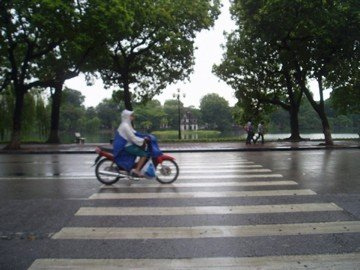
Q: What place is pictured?
A: It is a road.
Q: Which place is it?
A: It is a road.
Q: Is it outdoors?
A: Yes, it is outdoors.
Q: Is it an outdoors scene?
A: Yes, it is outdoors.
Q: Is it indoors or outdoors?
A: It is outdoors.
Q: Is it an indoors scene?
A: No, it is outdoors.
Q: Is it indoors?
A: No, it is outdoors.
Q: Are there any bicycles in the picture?
A: Yes, there is a bicycle.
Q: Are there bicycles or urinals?
A: Yes, there is a bicycle.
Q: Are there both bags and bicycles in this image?
A: Yes, there are both a bicycle and a bag.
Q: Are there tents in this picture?
A: No, there are no tents.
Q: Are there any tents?
A: No, there are no tents.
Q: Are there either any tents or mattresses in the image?
A: No, there are no tents or mattresses.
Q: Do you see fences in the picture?
A: No, there are no fences.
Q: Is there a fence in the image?
A: No, there are no fences.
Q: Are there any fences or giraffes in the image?
A: No, there are no fences or giraffes.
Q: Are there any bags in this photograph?
A: Yes, there is a bag.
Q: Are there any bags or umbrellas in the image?
A: Yes, there is a bag.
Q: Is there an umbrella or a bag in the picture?
A: Yes, there is a bag.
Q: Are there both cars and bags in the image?
A: No, there is a bag but no cars.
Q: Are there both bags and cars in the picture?
A: No, there is a bag but no cars.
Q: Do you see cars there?
A: No, there are no cars.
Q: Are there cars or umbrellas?
A: No, there are no cars or umbrellas.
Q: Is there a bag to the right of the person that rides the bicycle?
A: Yes, there is a bag to the right of the person.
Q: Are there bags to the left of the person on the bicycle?
A: No, the bag is to the right of the person.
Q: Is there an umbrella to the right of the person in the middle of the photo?
A: No, there is a bag to the right of the person.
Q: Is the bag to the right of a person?
A: Yes, the bag is to the right of a person.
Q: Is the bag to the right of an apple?
A: No, the bag is to the right of a person.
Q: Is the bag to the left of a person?
A: No, the bag is to the right of a person.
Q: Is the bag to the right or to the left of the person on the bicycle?
A: The bag is to the right of the person.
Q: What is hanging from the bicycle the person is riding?
A: The bag is hanging from the bicycle.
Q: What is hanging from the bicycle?
A: The bag is hanging from the bicycle.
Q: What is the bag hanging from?
A: The bag is hanging from the bicycle.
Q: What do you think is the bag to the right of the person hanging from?
A: The bag is hanging from the bicycle.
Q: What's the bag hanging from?
A: The bag is hanging from the bicycle.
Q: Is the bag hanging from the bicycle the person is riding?
A: Yes, the bag is hanging from the bicycle.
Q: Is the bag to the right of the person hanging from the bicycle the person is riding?
A: Yes, the bag is hanging from the bicycle.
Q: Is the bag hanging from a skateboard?
A: No, the bag is hanging from the bicycle.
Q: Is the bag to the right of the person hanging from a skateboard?
A: No, the bag is hanging from the bicycle.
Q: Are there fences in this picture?
A: No, there are no fences.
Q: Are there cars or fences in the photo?
A: No, there are no fences or cars.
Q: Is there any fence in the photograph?
A: No, there are no fences.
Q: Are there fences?
A: No, there are no fences.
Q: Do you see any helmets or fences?
A: No, there are no fences or helmets.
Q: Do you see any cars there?
A: No, there are no cars.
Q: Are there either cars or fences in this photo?
A: No, there are no cars or fences.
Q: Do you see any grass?
A: Yes, there is grass.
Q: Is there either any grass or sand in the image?
A: Yes, there is grass.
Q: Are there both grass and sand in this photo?
A: No, there is grass but no sand.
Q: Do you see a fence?
A: No, there are no fences.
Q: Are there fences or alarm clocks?
A: No, there are no fences or alarm clocks.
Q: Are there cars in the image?
A: No, there are no cars.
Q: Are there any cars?
A: No, there are no cars.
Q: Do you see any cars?
A: No, there are no cars.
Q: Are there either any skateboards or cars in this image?
A: No, there are no cars or skateboards.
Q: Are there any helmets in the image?
A: No, there are no helmets.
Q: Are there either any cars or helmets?
A: No, there are no helmets or cars.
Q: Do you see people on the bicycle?
A: Yes, there is a person on the bicycle.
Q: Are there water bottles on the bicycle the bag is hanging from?
A: No, there is a person on the bicycle.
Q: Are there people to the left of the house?
A: Yes, there is a person to the left of the house.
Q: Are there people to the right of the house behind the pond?
A: No, the person is to the left of the house.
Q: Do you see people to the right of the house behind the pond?
A: No, the person is to the left of the house.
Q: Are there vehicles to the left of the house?
A: No, there is a person to the left of the house.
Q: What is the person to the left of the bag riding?
A: The person is riding the bicycle.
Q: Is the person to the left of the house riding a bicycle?
A: Yes, the person is riding a bicycle.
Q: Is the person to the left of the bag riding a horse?
A: No, the person is riding a bicycle.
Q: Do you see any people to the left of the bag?
A: Yes, there is a person to the left of the bag.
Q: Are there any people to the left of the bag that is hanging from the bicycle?
A: Yes, there is a person to the left of the bag.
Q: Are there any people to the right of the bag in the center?
A: No, the person is to the left of the bag.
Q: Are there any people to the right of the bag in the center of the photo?
A: No, the person is to the left of the bag.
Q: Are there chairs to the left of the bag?
A: No, there is a person to the left of the bag.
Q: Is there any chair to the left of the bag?
A: No, there is a person to the left of the bag.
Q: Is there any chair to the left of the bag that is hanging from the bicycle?
A: No, there is a person to the left of the bag.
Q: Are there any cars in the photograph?
A: No, there are no cars.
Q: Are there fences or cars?
A: No, there are no cars or fences.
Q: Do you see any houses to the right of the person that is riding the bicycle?
A: Yes, there is a house to the right of the person.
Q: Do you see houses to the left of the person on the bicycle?
A: No, the house is to the right of the person.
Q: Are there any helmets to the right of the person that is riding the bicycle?
A: No, there is a house to the right of the person.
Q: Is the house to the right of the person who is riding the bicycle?
A: Yes, the house is to the right of the person.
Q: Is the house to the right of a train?
A: No, the house is to the right of the person.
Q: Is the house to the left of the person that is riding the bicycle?
A: No, the house is to the right of the person.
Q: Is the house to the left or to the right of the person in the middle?
A: The house is to the right of the person.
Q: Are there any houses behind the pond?
A: Yes, there is a house behind the pond.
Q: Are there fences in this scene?
A: No, there are no fences.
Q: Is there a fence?
A: No, there are no fences.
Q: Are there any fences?
A: No, there are no fences.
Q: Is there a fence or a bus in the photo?
A: No, there are no fences or buses.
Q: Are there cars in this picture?
A: No, there are no cars.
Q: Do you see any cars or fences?
A: No, there are no cars or fences.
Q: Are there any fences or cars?
A: No, there are no cars or fences.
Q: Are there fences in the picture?
A: No, there are no fences.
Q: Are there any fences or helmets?
A: No, there are no fences or helmets.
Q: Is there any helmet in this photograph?
A: No, there are no helmets.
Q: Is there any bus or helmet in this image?
A: No, there are no helmets or buses.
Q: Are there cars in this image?
A: No, there are no cars.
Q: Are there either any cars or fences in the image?
A: No, there are no cars or fences.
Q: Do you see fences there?
A: No, there are no fences.